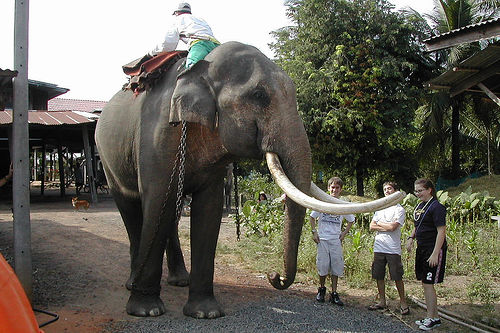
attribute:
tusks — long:
[253, 152, 404, 222]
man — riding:
[171, 0, 246, 90]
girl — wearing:
[392, 161, 474, 330]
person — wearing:
[138, 0, 231, 74]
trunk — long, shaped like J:
[268, 209, 305, 290]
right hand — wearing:
[309, 228, 322, 246]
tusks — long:
[258, 151, 431, 252]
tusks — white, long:
[267, 189, 383, 235]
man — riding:
[116, 0, 264, 97]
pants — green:
[166, 1, 223, 72]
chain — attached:
[171, 118, 191, 231]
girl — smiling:
[409, 171, 454, 328]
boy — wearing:
[372, 180, 407, 316]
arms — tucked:
[365, 217, 399, 237]